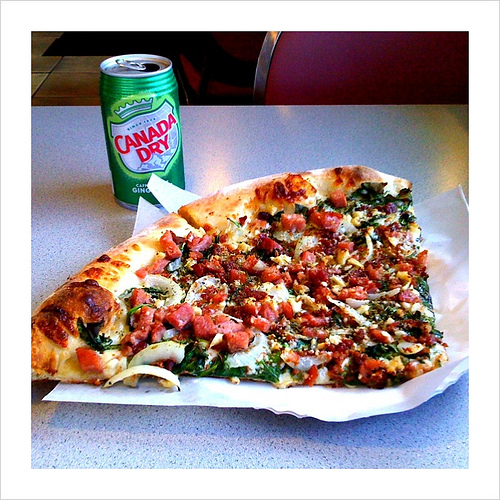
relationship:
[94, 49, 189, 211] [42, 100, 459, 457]
can sitting on table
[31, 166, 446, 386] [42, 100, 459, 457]
food sitting on table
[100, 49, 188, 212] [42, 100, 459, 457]
drink sitting on table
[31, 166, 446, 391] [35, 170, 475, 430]
food on paper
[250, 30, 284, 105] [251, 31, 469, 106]
frame on chair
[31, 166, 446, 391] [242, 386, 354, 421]
food on plate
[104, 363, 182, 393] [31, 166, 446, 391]
onion on food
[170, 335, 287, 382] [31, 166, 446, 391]
spinach on food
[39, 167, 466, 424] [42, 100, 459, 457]
plate on table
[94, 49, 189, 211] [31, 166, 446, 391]
can on food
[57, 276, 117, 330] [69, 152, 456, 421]
bubble on pizza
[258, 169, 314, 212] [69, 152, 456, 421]
bubble on pizza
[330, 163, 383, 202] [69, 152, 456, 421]
bubble on pizza